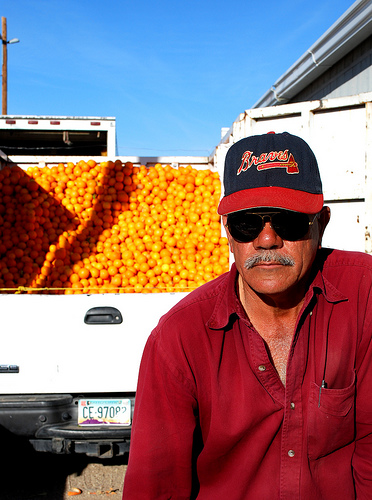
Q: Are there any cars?
A: No, there are no cars.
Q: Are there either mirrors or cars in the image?
A: No, there are no cars or mirrors.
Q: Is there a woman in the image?
A: No, there are no women.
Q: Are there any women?
A: No, there are no women.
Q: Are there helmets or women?
A: No, there are no women or helmets.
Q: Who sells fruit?
A: The man sells fruit.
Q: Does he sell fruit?
A: Yes, the man sells fruit.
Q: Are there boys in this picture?
A: No, there are no boys.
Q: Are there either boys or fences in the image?
A: No, there are no boys or fences.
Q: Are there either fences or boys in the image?
A: No, there are no boys or fences.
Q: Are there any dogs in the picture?
A: No, there are no dogs.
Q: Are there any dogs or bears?
A: No, there are no dogs or bears.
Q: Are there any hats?
A: Yes, there is a hat.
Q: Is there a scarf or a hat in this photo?
A: Yes, there is a hat.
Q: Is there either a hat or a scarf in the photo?
A: Yes, there is a hat.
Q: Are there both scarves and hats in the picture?
A: No, there is a hat but no scarves.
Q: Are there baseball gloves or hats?
A: Yes, there is a baseball hat.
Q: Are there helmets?
A: No, there are no helmets.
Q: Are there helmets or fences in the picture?
A: No, there are no helmets or fences.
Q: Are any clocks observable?
A: No, there are no clocks.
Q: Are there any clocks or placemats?
A: No, there are no clocks or placemats.